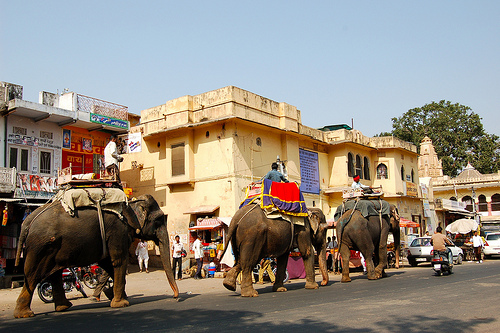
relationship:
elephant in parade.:
[339, 195, 402, 284] [8, 185, 500, 321]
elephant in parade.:
[217, 199, 333, 296] [8, 185, 500, 321]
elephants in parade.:
[11, 191, 180, 320] [8, 185, 500, 321]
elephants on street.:
[11, 191, 398, 319] [12, 255, 500, 331]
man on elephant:
[351, 175, 382, 195] [339, 195, 402, 284]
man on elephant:
[252, 162, 291, 186] [217, 199, 333, 296]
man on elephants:
[103, 134, 124, 192] [11, 191, 180, 320]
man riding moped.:
[434, 228, 450, 254] [429, 243, 454, 277]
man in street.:
[170, 234, 184, 281] [12, 255, 500, 331]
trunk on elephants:
[142, 202, 188, 300] [11, 191, 180, 320]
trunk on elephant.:
[318, 226, 333, 287] [217, 199, 333, 296]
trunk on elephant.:
[392, 210, 402, 272] [339, 195, 402, 284]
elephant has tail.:
[339, 195, 402, 284] [334, 212, 350, 257]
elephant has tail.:
[217, 199, 333, 296] [215, 218, 240, 267]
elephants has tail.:
[11, 191, 180, 320] [13, 216, 38, 267]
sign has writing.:
[301, 141, 315, 199] [305, 155, 318, 186]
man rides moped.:
[434, 228, 450, 254] [429, 243, 454, 277]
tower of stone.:
[419, 132, 447, 180] [421, 157, 443, 174]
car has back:
[411, 241, 460, 262] [409, 235, 440, 263]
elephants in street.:
[11, 191, 398, 319] [12, 255, 500, 331]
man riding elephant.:
[351, 176, 366, 202] [339, 195, 402, 284]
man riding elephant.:
[268, 165, 289, 186] [217, 199, 333, 296]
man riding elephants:
[107, 132, 125, 185] [11, 191, 180, 320]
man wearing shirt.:
[473, 234, 485, 260] [471, 236, 486, 249]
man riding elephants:
[252, 162, 291, 186] [11, 191, 398, 319]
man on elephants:
[107, 132, 125, 185] [11, 191, 180, 320]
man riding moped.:
[434, 228, 450, 254] [427, 250, 462, 277]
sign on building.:
[301, 141, 315, 199] [123, 88, 440, 262]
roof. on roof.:
[135, 78, 424, 156] [135, 78, 424, 156]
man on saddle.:
[351, 176, 366, 202] [346, 180, 401, 203]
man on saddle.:
[268, 165, 289, 186] [254, 180, 318, 218]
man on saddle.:
[107, 132, 125, 185] [58, 163, 124, 186]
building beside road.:
[123, 88, 440, 262] [12, 255, 500, 331]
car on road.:
[406, 236, 464, 265] [12, 255, 500, 331]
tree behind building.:
[384, 102, 499, 174] [408, 129, 498, 270]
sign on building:
[301, 141, 315, 199] [123, 88, 440, 262]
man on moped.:
[434, 228, 450, 254] [429, 243, 454, 277]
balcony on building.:
[59, 144, 129, 189] [0, 85, 130, 236]